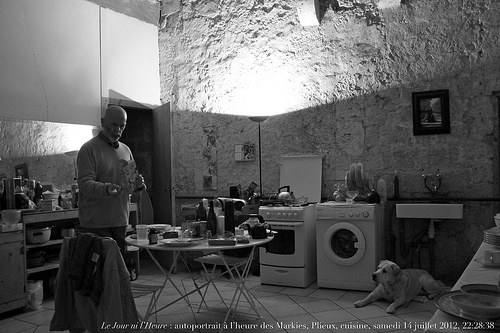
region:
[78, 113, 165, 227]
this is a man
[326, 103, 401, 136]
this is the wall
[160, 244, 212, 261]
this is a table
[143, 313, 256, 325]
this is a writing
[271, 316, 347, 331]
the writing is in white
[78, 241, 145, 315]
this is a chair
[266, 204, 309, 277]
this is a microwave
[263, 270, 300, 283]
the microwave is white in color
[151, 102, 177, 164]
this is a door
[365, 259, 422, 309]
this is a dog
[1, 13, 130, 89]
the wall is white in colour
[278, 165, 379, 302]
washing machines are near the wall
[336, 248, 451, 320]
a dog is lying near the wall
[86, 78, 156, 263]
an old man is standing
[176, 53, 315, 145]
the lights are on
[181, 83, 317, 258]
the cooker is open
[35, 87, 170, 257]
the man has a can on his hands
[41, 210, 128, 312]
a jacket is on the chair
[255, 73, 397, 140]
the wall is course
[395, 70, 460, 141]
a portrait is on the wall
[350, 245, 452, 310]
A dog sitting on the floor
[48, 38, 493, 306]
The photo is taken in black and white.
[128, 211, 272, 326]
A round table in middle of room.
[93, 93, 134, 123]
The man has a bald head.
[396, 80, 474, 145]
A picture is on the wall.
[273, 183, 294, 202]
Teapot on top of the stove.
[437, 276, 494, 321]
Plate and bowls on the countertop.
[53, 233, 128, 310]
A jacket hanging over the chair.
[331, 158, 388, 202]
Dishes on top of the appliance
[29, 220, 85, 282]
Pots on the shelves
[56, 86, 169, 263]
man standing by table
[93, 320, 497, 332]
photo copyright on lower corner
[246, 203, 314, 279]
stone near wall on back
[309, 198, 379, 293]
washing machine near wall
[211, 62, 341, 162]
light shining off rear wall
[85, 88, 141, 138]
bald head of man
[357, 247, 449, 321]
small dog on tile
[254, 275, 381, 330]
tile flooring of room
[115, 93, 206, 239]
open door on left wall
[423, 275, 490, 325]
small plate on right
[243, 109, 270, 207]
illuminated pedestal lamp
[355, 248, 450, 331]
a dog looking at it's master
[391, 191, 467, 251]
white sink on the wall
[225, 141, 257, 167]
callendar under a lamp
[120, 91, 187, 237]
open door leading out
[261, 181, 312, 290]
stove with a tea kettle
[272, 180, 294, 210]
shiny tea kettle on a stove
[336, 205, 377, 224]
knobs on a washing machine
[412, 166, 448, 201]
two sing faucets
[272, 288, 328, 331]
tiled floor in a kitchen